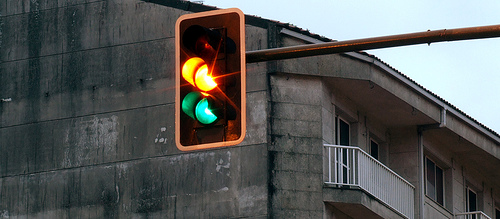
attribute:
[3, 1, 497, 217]
building — grey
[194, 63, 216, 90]
light — lit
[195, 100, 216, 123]
light — lit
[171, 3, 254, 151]
signal — traffic